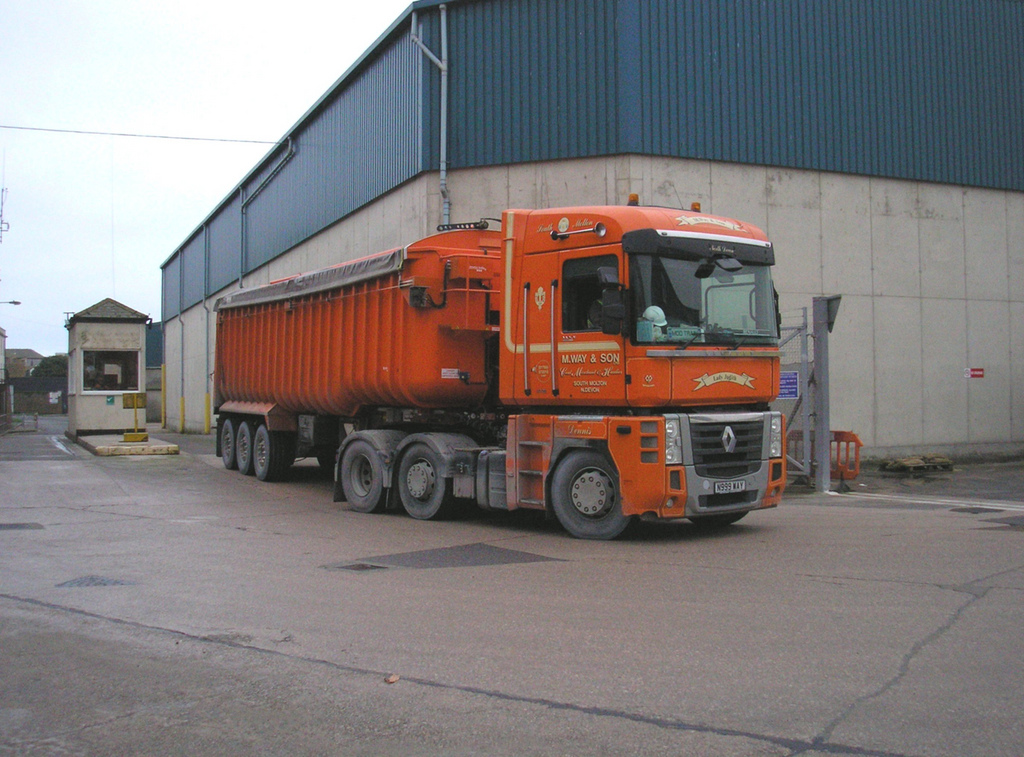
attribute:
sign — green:
[98, 396, 103, 407]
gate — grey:
[772, 318, 900, 452]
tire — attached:
[371, 420, 519, 563]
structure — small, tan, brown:
[61, 294, 154, 437]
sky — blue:
[3, 5, 405, 358]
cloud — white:
[3, 3, 408, 323]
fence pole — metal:
[800, 283, 852, 507]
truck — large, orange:
[203, 187, 795, 542]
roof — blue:
[158, 5, 1020, 316]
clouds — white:
[36, 22, 122, 96]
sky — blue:
[17, 11, 252, 189]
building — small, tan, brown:
[59, 291, 160, 451]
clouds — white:
[68, 227, 149, 280]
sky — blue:
[12, 54, 159, 283]